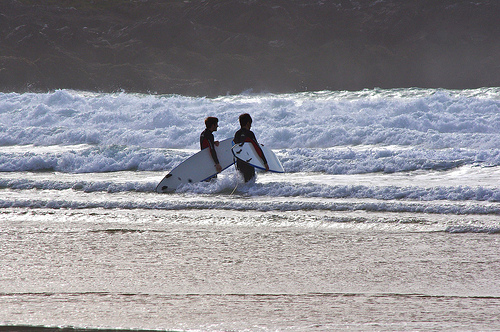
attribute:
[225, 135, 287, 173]
surfboard — white 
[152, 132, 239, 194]
surfboard — white 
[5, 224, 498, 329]
water — shallow, brown, sandy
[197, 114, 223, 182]
man — young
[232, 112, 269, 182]
man — young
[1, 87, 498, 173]
waves — white, foamy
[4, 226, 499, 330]
calm water — calmer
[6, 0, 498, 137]
water — grey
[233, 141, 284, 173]
surfboard — white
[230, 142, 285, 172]
surfboard — white 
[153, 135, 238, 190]
surfboard — white 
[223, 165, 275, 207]
cord — white